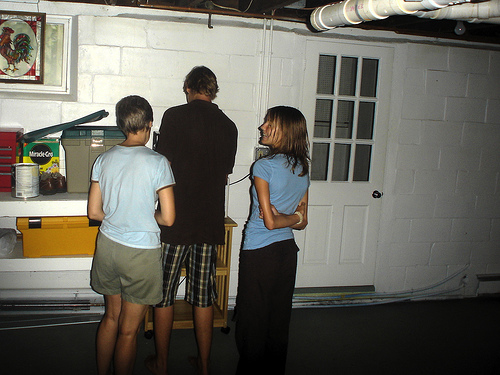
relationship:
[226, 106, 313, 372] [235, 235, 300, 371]
girl wearing pants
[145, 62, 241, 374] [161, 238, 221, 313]
man wearing shorts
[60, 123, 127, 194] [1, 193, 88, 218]
container on table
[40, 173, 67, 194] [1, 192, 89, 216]
shoes on counter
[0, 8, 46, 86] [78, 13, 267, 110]
painting on wall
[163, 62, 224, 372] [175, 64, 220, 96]
man has hair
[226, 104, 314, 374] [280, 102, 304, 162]
girl has hair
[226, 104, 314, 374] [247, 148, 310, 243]
girl wearing a shirt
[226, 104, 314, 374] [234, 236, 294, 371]
girl wearing a pants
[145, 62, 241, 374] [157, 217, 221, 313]
man wearing a shorts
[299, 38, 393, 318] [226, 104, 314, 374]
door behind girl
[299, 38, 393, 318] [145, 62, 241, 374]
door behind man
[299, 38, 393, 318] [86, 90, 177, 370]
door behind person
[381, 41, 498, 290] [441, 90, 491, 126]
wall made of brick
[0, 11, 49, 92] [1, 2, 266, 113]
painting hanging on wall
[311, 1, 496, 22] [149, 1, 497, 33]
pipe on ceiling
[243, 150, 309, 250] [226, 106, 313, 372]
t-shirt on girl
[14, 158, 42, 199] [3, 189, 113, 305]
can on table